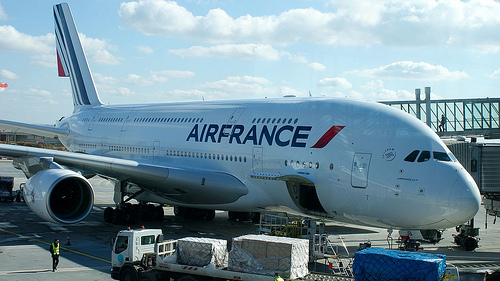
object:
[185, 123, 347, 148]
logo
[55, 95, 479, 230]
side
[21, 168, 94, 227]
engine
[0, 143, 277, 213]
wing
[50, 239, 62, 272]
man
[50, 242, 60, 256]
vest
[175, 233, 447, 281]
cargo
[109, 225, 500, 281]
truck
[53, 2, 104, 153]
tail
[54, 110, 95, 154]
back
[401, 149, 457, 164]
cockpit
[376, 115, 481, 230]
front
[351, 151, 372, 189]
door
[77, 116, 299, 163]
group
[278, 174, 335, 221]
cargo door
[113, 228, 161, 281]
cab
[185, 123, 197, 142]
letter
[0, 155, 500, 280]
ground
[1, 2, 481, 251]
airplane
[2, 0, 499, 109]
clouds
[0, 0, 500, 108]
sky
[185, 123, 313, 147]
writing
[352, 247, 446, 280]
luggage carrier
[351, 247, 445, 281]
blue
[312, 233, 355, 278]
walkway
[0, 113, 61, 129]
hills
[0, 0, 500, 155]
distance